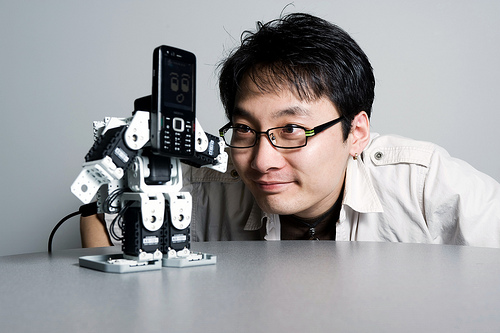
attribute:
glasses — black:
[215, 124, 324, 151]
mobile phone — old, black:
[152, 42, 195, 162]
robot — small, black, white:
[75, 46, 231, 272]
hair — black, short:
[207, 19, 388, 129]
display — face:
[162, 60, 197, 107]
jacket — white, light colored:
[98, 138, 498, 239]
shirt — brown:
[275, 217, 337, 247]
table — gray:
[5, 239, 499, 327]